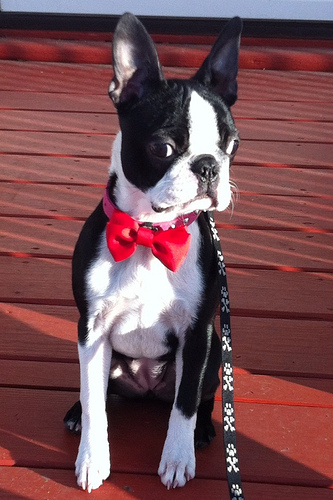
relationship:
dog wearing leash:
[63, 12, 246, 488] [203, 207, 254, 498]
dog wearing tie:
[63, 12, 246, 488] [105, 210, 190, 273]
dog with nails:
[63, 12, 246, 488] [159, 469, 180, 498]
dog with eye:
[63, 12, 246, 488] [151, 141, 177, 157]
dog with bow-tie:
[63, 12, 246, 488] [102, 191, 200, 270]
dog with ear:
[63, 12, 246, 488] [202, 9, 244, 107]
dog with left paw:
[63, 12, 246, 488] [149, 441, 200, 487]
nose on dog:
[192, 157, 225, 183] [61, 20, 266, 491]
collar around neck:
[98, 187, 203, 233] [89, 167, 209, 236]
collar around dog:
[98, 187, 203, 233] [63, 12, 246, 488]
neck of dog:
[89, 167, 209, 236] [63, 12, 246, 488]